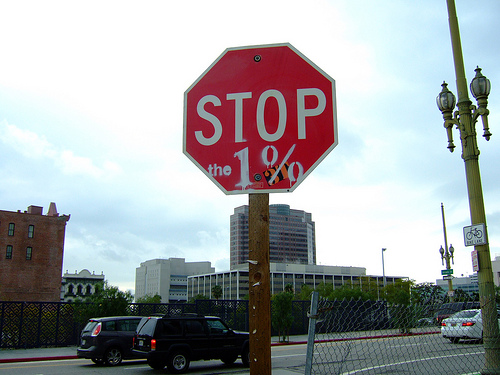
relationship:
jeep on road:
[131, 305, 251, 372] [1, 326, 498, 373]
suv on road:
[65, 314, 132, 363] [1, 326, 498, 373]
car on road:
[434, 307, 488, 343] [1, 326, 498, 373]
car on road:
[434, 307, 460, 327] [1, 326, 498, 373]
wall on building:
[4, 219, 60, 317] [11, 206, 71, 298]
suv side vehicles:
[65, 314, 132, 363] [128, 307, 253, 374]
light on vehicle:
[129, 336, 136, 349] [128, 313, 248, 373]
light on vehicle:
[150, 338, 155, 350] [128, 313, 248, 373]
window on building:
[4, 219, 22, 241] [0, 203, 72, 346]